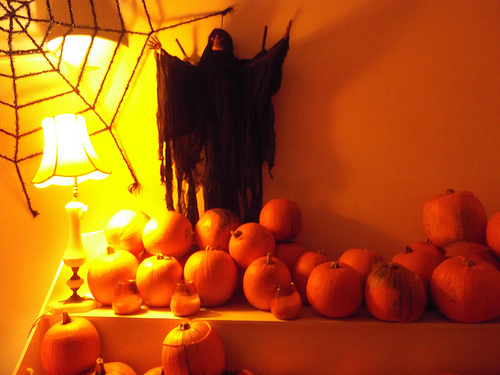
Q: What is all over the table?
A: Pumpkins.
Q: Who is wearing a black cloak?
A: Grim reaper.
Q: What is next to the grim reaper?
A: Cobweb.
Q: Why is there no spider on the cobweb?
A: Decoration.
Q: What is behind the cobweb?
A: Light.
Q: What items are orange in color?
A: Pumpkins.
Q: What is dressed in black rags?
A: A white skeleton.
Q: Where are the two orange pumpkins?
A: On the shelf.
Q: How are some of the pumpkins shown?
A: Stacked on each other.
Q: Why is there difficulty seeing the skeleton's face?
A: Dim lighting.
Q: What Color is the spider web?
A: Black.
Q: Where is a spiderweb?
A: Upper left corner.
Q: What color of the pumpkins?
A: Orange.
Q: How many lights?
A: One.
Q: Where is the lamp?
A: Next to the pumpkins.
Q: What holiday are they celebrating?
A: Halloween.